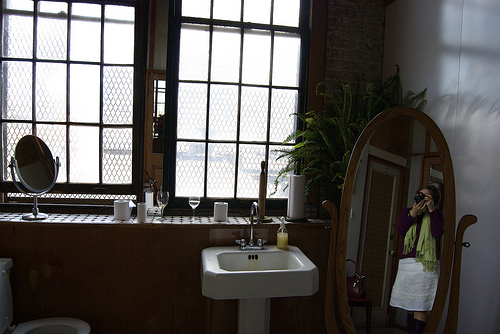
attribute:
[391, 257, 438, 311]
skirt — white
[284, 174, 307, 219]
paper towel — white, in roll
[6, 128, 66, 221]
mirror — wooden, dark brown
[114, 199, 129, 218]
paper — white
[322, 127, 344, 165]
ground — wood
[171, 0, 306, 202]
window — large, brown paned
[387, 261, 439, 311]
skirt — cotton, woman's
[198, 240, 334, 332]
sink — white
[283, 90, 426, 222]
floor plant — green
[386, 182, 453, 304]
person — reflection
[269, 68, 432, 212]
plant — potted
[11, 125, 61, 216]
mirror — small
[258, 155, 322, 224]
towels — paper, a roll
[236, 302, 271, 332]
pedestal — white, porcelain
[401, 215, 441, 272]
scarf — green, in reflection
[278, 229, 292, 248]
bottle — soap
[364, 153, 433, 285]
mirror — oval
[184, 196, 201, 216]
liquid — clear